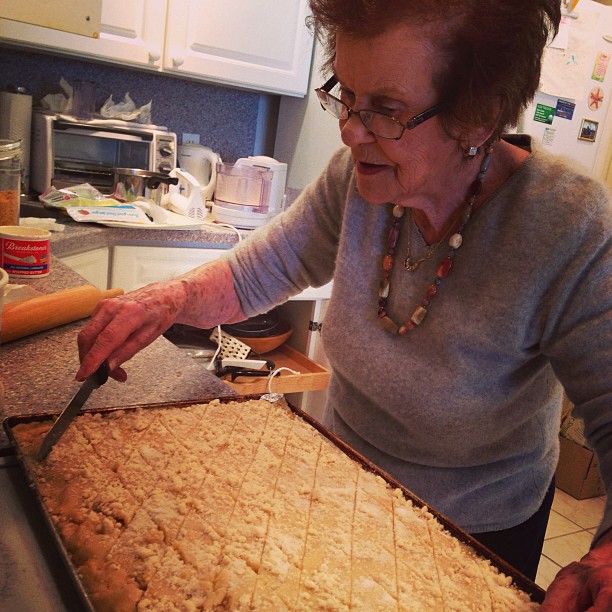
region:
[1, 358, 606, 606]
knife point is touching a baked good in a long baking sheet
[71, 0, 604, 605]
woman is wearing a long necklace made of beads of assorted colors and shapes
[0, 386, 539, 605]
baked good has slits crisscrossed throughout its surface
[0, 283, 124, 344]
a wooden rolling pin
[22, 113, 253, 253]
toaster oven on counter top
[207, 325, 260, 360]
a food grater on its side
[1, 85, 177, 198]
roll of paper towels beside toaster oven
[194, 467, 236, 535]
piece of flaky pastry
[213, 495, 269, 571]
piece of flaky pastry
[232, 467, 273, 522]
piece of flaky pastry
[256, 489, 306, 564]
piece of flaky pastry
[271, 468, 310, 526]
piece of flaky pastry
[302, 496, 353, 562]
piece of flaky pastry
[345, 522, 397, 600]
piece of flaky pastry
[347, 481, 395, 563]
piece of flaky pastry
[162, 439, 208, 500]
piece of flaky pastry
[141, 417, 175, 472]
piece of flaky pastry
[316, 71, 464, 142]
Black framed glasses on a face.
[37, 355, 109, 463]
A black handled silver knife.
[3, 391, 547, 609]
A brown and silver rectangle pan.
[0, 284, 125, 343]
A brown rolling pin.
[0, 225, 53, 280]
A mostly red round container of icing.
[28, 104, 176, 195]
A white and silver toaster oven.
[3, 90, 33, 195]
White roll of paper towels.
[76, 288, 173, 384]
A womans right hand.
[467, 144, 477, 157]
Square diamond earring.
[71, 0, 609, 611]
woman wearing a gray shirt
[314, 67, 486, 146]
dark pair of eyeglasses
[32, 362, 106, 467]
knife cutting into baked goods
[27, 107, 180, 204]
white and silver microwave oven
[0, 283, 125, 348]
brown wooden rolling pin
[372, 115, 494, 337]
large beads on a necklace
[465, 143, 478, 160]
diamond shaped earring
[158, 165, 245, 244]
white hand mixer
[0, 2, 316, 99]
closed white cupboard doors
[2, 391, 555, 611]
tray of baked goods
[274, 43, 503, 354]
a woman in the ktichen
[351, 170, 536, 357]
a woman wearing a necklace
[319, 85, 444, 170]
a woman wearing glasses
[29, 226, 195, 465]
a woman holding a knife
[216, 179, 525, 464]
a woman wearing a shirt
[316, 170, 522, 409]
a woman a long sleeve shirt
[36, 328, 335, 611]
a tray of food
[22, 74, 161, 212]
a toaster oven on the counter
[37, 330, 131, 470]
woman cutting into the cake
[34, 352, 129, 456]
woman holding a knife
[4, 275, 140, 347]
rolling pin on the counter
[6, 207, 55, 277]
cup of butter on the counter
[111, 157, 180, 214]
pot on top of the counter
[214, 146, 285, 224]
food processor on the counter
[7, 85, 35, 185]
roll of towel on the counter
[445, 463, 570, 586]
woman wearing black pants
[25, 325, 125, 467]
blade of a knife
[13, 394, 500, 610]
cut marks on a cake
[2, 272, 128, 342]
rolling pin on a counter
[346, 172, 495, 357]
woman wearing a necklace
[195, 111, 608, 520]
woman wearing a gray shirt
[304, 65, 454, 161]
a pair of glasses